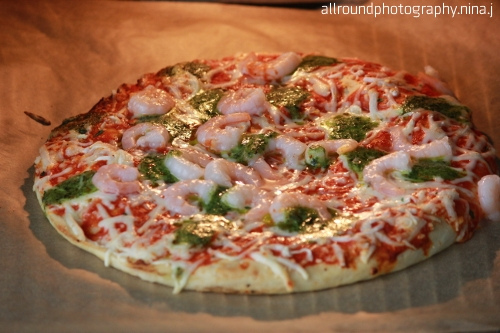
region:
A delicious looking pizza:
[38, 87, 485, 257]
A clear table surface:
[414, 260, 479, 330]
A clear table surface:
[288, 291, 362, 331]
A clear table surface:
[178, 294, 265, 331]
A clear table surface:
[1, 237, 52, 329]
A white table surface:
[92, 8, 182, 58]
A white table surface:
[252, 5, 333, 49]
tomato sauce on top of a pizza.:
[99, 102, 124, 132]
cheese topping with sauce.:
[321, 71, 388, 120]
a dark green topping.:
[266, 83, 307, 120]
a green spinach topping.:
[327, 109, 379, 144]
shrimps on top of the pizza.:
[192, 109, 257, 158]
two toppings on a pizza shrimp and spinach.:
[173, 110, 403, 196]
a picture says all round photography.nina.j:
[314, 0, 499, 23]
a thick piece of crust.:
[206, 251, 306, 295]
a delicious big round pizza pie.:
[1, 27, 499, 332]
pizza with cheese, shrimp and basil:
[37, 43, 493, 310]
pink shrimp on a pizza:
[113, 120, 255, 232]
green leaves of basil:
[322, 102, 377, 178]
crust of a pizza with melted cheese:
[93, 230, 425, 288]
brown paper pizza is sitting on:
[42, 13, 472, 53]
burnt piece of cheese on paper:
[15, 88, 56, 131]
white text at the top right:
[312, 5, 497, 19]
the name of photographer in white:
[457, 3, 494, 20]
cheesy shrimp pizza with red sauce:
[65, 62, 474, 294]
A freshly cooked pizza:
[23, 41, 497, 313]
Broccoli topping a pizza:
[317, 108, 385, 140]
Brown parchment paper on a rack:
[404, 273, 490, 322]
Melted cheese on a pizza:
[233, 233, 303, 261]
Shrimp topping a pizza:
[202, 157, 257, 194]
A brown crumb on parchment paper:
[19, 106, 53, 129]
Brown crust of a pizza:
[192, 262, 376, 302]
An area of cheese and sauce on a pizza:
[88, 202, 158, 239]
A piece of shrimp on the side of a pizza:
[470, 165, 499, 240]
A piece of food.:
[317, 176, 329, 190]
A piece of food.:
[288, 140, 335, 162]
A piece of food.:
[350, 150, 380, 174]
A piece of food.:
[233, 133, 281, 161]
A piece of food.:
[203, 182, 240, 213]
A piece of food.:
[135, 145, 145, 150]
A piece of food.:
[235, 80, 295, 123]